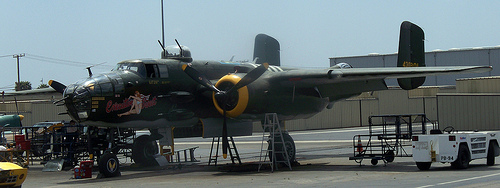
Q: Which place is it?
A: It is an airport.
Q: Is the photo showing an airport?
A: Yes, it is showing an airport.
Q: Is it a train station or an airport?
A: It is an airport.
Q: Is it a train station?
A: No, it is an airport.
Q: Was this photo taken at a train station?
A: No, the picture was taken in an airport.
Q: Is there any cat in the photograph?
A: No, there are no cats.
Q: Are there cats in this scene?
A: No, there are no cats.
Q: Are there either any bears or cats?
A: No, there are no cats or bears.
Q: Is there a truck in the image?
A: No, there are no trucks.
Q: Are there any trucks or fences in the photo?
A: No, there are no trucks or fences.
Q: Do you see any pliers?
A: No, there are no pliers.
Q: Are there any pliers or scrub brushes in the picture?
A: No, there are no pliers or scrub brushes.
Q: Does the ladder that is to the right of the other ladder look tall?
A: Yes, the ladder is tall.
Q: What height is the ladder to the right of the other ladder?
A: The ladder is tall.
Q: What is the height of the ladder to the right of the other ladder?
A: The ladder is tall.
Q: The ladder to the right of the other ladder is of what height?
A: The ladder is tall.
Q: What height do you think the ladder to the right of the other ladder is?
A: The ladder is tall.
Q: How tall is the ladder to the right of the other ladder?
A: The ladder is tall.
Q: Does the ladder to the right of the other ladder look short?
A: No, the ladder is tall.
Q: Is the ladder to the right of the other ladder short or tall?
A: The ladder is tall.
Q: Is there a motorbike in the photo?
A: No, there are no motorcycles.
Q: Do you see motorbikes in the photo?
A: No, there are no motorbikes.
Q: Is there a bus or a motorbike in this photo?
A: No, there are no motorcycles or buses.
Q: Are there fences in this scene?
A: No, there are no fences.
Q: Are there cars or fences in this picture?
A: No, there are no fences or cars.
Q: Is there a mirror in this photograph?
A: No, there are no mirrors.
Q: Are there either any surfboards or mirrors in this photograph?
A: No, there are no mirrors or surfboards.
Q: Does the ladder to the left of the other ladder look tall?
A: Yes, the ladder is tall.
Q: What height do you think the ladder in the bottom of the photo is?
A: The ladder is tall.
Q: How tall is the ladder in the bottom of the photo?
A: The ladder is tall.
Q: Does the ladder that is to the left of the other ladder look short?
A: No, the ladder is tall.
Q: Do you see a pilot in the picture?
A: No, there are no pilots.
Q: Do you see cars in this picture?
A: No, there are no cars.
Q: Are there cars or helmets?
A: No, there are no cars or helmets.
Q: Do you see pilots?
A: No, there are no pilots.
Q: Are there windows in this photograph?
A: Yes, there is a window.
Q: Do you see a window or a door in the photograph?
A: Yes, there is a window.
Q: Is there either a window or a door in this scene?
A: Yes, there is a window.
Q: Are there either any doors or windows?
A: Yes, there is a window.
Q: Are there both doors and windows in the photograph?
A: No, there is a window but no doors.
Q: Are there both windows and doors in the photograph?
A: No, there is a window but no doors.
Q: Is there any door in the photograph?
A: No, there are no doors.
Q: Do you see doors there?
A: No, there are no doors.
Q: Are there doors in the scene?
A: No, there are no doors.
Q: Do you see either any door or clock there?
A: No, there are no doors or clocks.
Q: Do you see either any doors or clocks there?
A: No, there are no doors or clocks.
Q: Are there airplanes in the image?
A: Yes, there is an airplane.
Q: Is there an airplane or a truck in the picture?
A: Yes, there is an airplane.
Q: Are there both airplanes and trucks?
A: No, there is an airplane but no trucks.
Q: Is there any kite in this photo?
A: No, there are no kites.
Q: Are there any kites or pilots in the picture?
A: No, there are no kites or pilots.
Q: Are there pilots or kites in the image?
A: No, there are no kites or pilots.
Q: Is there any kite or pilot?
A: No, there are no kites or pilots.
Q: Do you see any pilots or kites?
A: No, there are no kites or pilots.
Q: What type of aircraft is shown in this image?
A: The aircraft is an airplane.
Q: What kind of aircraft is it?
A: The aircraft is an airplane.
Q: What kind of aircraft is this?
A: This is an airplane.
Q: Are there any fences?
A: No, there are no fences.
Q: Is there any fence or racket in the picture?
A: No, there are no fences or rackets.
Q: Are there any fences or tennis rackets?
A: No, there are no fences or tennis rackets.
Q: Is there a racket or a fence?
A: No, there are no fences or rackets.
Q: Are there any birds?
A: No, there are no birds.